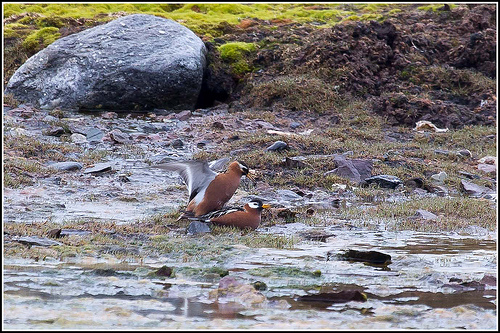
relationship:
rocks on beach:
[7, 104, 500, 201] [0, 110, 500, 252]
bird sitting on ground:
[147, 157, 255, 219] [11, 108, 499, 331]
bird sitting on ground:
[188, 200, 269, 234] [11, 108, 499, 331]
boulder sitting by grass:
[3, 14, 209, 114] [3, 2, 374, 39]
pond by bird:
[0, 231, 498, 333] [148, 156, 234, 223]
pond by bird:
[0, 231, 498, 333] [194, 175, 286, 245]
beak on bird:
[262, 204, 272, 209] [204, 197, 271, 231]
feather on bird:
[151, 160, 218, 199] [147, 157, 255, 219]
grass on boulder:
[3, 2, 374, 39] [3, 14, 209, 114]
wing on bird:
[145, 156, 206, 216] [159, 155, 259, 227]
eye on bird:
[251, 201, 260, 206] [178, 154, 260, 225]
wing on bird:
[154, 159, 219, 198] [153, 130, 278, 216]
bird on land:
[150, 157, 255, 223] [40, 235, 478, 317]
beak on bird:
[260, 202, 270, 210] [201, 196, 270, 224]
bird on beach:
[150, 157, 255, 223] [66, 28, 455, 329]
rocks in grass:
[7, 104, 500, 201] [348, 97, 371, 138]